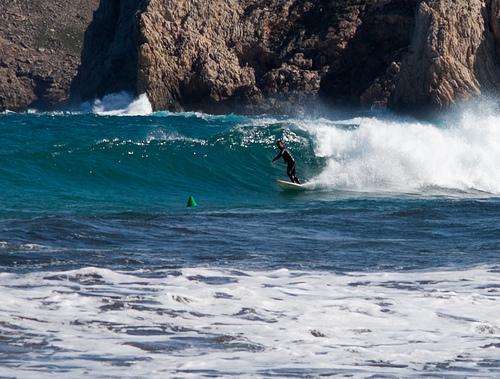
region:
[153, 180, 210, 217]
pointed green cone floating in water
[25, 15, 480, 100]
rough and tall natural stone wall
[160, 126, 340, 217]
surfer headed toward cone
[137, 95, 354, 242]
bright and sunny day while surfing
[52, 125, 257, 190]
smooth wall of cresting wave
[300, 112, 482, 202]
rough and churning crested wave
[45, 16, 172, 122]
water hitting against shadowy crevasse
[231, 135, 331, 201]
surfer upright and leaning right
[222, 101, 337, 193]
surfer in the curve of the wave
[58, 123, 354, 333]
water surface is different colors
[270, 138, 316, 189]
a man on a surfboard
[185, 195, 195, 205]
a green cone floating in the water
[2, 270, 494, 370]
foamy water near the shore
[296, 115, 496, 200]
a smal wave crashing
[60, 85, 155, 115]
wave crashing against the cliff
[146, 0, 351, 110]
jagged rick formation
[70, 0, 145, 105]
shadow cast by the cliff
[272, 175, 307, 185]
a surfboard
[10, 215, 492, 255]
calm waters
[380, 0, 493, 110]
protruding rock formation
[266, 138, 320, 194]
surfer on surfboard in water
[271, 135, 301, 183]
surfer wearing black wetsuit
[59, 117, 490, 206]
wave behind man surfing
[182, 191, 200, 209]
green cone in water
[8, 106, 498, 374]
bright blue water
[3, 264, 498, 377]
white foam on surface of water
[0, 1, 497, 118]
steep rock at edge of water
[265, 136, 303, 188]
surfer leaning over on surfboard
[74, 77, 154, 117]
water splashing between rocks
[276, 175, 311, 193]
light-colored surfboard in water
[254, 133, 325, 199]
a person on a surfboard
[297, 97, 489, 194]
a breaking wave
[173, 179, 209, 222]
a green buoy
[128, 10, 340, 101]
large rocks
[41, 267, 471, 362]
white foamy water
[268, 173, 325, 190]
a surfboard in the water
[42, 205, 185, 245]
some clear blue water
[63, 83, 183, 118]
a wave breaking on the rocks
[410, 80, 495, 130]
the spray from the breaking wave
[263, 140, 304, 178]
a person wearing a wetsuit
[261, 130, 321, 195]
person surfing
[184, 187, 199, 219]
a green cone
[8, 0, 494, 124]
rocky landscape in background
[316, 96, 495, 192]
huge wave with white caps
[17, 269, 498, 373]
calm waves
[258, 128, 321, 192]
surfer is wearing a black wet suit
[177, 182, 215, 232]
danger cone alerting to rocks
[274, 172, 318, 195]
white surf board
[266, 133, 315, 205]
surfer is coming down from the wave and has hands extended outward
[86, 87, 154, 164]
rough water splashing on rocks